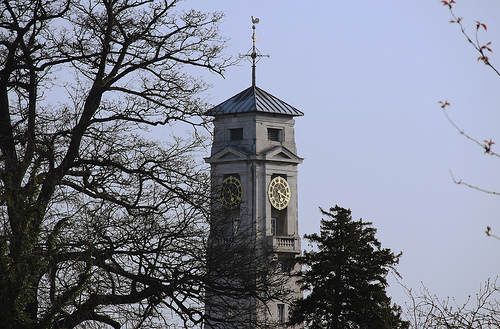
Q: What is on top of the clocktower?
A: A wind reader.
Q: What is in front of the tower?
A: A tree.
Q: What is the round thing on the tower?
A: A clock.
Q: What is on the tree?
A: Branches.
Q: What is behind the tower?
A: The sky.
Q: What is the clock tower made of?
A: Stone.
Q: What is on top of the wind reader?
A: A chicken.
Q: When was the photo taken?
A: Daytime.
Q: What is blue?
A: Sky.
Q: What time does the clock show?
A: 5:18.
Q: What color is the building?
A: Gray.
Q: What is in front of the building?
A: Trees.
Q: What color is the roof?
A: Black.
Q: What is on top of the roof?
A: Weathervane.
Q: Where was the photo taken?
A: Close to clock.